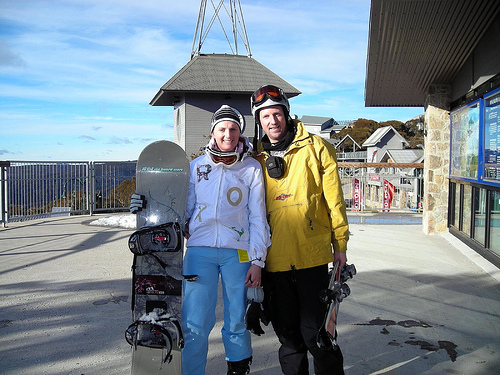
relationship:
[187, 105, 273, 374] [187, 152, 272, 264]
woman wears a white jacket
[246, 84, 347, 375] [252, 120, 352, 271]
man wears a yellow jacket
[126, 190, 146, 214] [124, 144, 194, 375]
glove on a snowboard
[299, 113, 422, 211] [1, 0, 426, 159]
houses and sky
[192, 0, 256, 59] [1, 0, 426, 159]
tower base against sky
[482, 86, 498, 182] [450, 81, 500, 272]
schedule in window]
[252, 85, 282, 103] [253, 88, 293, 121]
goggles on helmet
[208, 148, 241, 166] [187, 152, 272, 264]
white goggles and white jacket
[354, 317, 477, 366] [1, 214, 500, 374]
stain on pavement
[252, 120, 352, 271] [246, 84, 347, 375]
yellow jacket on a man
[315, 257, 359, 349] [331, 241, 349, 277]
skis in hand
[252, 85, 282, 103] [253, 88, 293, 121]
black goggles on helmet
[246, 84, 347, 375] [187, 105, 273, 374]
man and a woman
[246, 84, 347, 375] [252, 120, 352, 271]
man in a yellow jacket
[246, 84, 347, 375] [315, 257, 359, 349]
man carries skis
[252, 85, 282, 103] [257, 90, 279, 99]
goggles with red lenses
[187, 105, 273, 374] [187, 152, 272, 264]
woman wearing a white jacket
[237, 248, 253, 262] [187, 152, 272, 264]
ski lift ticket on white jacket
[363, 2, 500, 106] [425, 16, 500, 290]
eave of building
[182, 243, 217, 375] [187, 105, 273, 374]
leg of a woman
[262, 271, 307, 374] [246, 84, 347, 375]
leg of a man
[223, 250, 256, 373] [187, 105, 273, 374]
leg of a woman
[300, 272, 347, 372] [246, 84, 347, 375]
leg of a man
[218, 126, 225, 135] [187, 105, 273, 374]
eye on woman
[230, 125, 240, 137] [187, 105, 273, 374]
left eye of a woman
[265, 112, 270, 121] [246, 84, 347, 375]
right eye of a man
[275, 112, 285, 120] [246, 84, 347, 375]
left eye of a man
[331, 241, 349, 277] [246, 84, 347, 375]
hand of a man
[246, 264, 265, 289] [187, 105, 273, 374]
left hand of a woman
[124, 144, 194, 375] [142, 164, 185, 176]
snowboard with green print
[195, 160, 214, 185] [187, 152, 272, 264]
design on white jacket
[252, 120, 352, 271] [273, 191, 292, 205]
yellow jacket has a logo